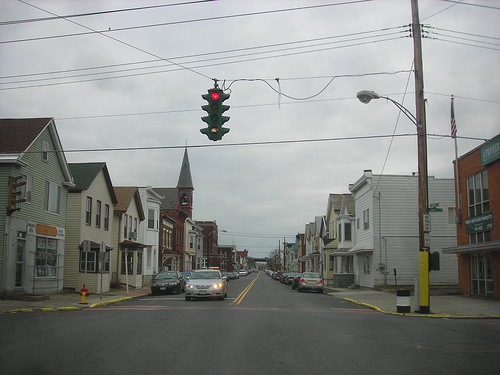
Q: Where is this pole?
A: On the corner of a street.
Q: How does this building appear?
A: Red.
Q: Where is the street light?
A: On a pole.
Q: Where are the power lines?
A: Above the street.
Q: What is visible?
A: The street.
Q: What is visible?
A: The street.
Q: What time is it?
A: Afternoon.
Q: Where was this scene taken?
A: Gilroy.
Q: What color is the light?
A: Red.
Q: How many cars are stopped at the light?
A: One.